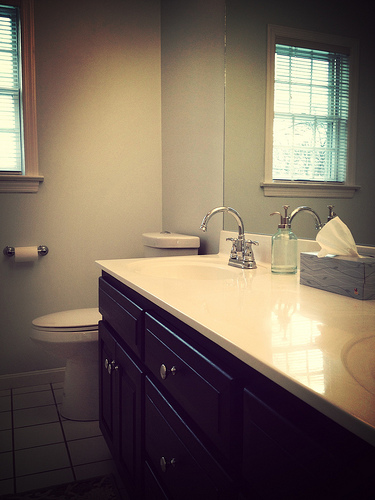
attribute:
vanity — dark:
[95, 229, 374, 447]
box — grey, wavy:
[297, 250, 374, 301]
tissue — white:
[316, 215, 366, 260]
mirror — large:
[223, 3, 374, 248]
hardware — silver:
[101, 357, 178, 473]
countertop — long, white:
[93, 230, 375, 448]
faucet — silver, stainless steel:
[199, 206, 259, 272]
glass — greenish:
[269, 226, 301, 276]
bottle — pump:
[268, 204, 300, 276]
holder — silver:
[4, 245, 47, 258]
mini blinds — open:
[0, 4, 24, 175]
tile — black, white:
[3, 380, 359, 499]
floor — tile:
[1, 380, 126, 499]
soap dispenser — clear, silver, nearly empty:
[269, 204, 301, 276]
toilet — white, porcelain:
[30, 230, 201, 424]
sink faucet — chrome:
[200, 206, 258, 271]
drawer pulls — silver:
[100, 357, 179, 475]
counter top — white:
[95, 229, 374, 447]